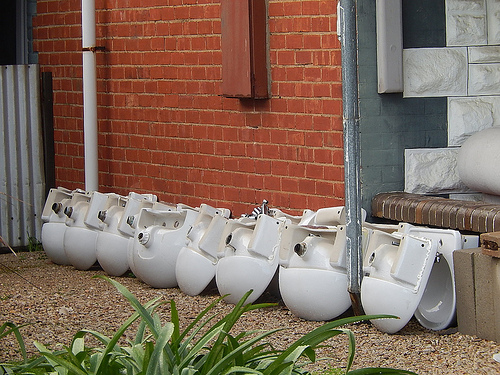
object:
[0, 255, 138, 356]
dirt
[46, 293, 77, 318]
stone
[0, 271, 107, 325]
gravel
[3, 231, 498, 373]
ground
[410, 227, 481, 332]
sink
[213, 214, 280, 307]
sink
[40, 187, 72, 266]
sink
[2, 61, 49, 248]
fencing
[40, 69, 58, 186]
shadow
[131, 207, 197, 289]
white objects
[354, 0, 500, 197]
wall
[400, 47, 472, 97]
block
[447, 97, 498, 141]
block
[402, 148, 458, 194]
block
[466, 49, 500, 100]
block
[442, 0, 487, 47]
block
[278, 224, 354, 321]
sink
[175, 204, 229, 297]
sink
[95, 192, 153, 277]
sink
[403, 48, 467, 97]
molds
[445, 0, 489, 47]
molds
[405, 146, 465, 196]
molds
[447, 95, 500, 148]
molds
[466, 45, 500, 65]
molds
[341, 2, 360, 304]
pipe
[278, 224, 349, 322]
washbasin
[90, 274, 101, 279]
tip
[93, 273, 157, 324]
leaf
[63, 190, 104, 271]
sink bowls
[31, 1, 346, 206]
wall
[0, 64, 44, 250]
sheeting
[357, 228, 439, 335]
sink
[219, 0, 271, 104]
box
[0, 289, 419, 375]
grass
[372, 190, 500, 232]
porch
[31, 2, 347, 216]
brick wall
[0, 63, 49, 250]
fence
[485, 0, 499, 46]
tiles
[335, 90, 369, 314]
downspout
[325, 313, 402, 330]
leaves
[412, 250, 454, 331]
white sinks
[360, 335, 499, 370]
gravel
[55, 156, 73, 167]
bricks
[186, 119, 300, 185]
brick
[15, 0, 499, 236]
building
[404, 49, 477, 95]
brick